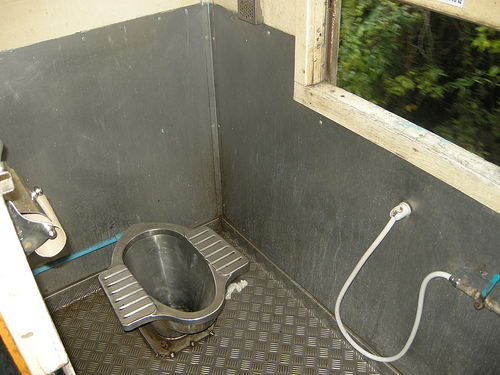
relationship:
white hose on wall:
[263, 173, 456, 336] [307, 169, 451, 346]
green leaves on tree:
[352, 17, 427, 80] [342, 7, 494, 139]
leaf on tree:
[351, 25, 365, 37] [354, 33, 467, 133]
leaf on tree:
[351, 25, 365, 37] [342, 7, 494, 139]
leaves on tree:
[386, 74, 409, 94] [342, 7, 494, 139]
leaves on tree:
[351, 30, 379, 53] [342, 7, 494, 139]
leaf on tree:
[351, 25, 365, 37] [359, 22, 479, 130]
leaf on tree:
[351, 25, 365, 37] [340, 0, 499, 159]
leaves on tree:
[333, 0, 499, 173] [418, 21, 498, 155]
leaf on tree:
[351, 25, 365, 37] [333, 0, 498, 172]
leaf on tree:
[351, 25, 365, 37] [344, 24, 405, 104]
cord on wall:
[331, 198, 457, 363] [44, 49, 195, 181]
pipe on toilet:
[33, 227, 125, 280] [94, 214, 259, 356]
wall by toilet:
[11, 53, 426, 283] [94, 214, 259, 356]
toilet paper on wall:
[23, 195, 67, 255] [17, 132, 80, 183]